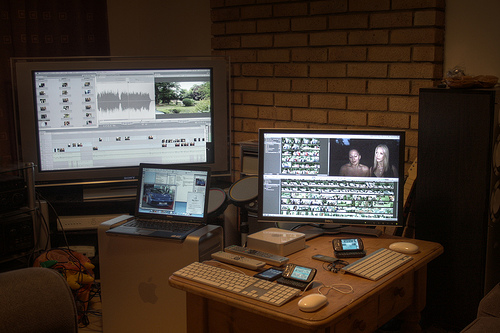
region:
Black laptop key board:
[123, 219, 198, 239]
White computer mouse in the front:
[297, 290, 329, 321]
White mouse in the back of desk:
[388, 237, 423, 255]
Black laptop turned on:
[107, 160, 208, 242]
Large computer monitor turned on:
[257, 128, 404, 223]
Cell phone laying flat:
[256, 264, 283, 284]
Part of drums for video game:
[207, 170, 259, 215]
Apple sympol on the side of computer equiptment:
[130, 264, 165, 309]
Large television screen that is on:
[8, 60, 233, 175]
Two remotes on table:
[212, 244, 288, 273]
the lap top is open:
[114, 155, 211, 246]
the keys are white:
[342, 224, 414, 281]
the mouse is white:
[292, 280, 339, 324]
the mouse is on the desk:
[277, 276, 342, 321]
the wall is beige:
[215, 13, 415, 175]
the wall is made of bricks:
[210, 10, 409, 157]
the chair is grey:
[0, 259, 87, 323]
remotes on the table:
[210, 237, 284, 271]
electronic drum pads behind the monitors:
[211, 170, 258, 220]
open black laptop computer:
[103, 160, 213, 243]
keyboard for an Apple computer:
[171, 260, 301, 308]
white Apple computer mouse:
[293, 285, 333, 316]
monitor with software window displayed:
[258, 129, 403, 224]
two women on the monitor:
[328, 136, 395, 179]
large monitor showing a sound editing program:
[34, 72, 214, 169]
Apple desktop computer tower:
[96, 208, 221, 331]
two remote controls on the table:
[210, 240, 285, 270]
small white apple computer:
[246, 223, 308, 258]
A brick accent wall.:
[217, 7, 432, 132]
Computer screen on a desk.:
[260, 131, 403, 226]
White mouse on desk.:
[296, 289, 328, 313]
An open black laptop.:
[109, 162, 219, 243]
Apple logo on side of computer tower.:
[134, 272, 160, 308]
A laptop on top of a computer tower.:
[104, 162, 214, 244]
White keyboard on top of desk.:
[174, 259, 300, 309]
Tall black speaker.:
[410, 85, 498, 325]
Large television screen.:
[13, 52, 231, 177]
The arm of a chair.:
[3, 259, 81, 329]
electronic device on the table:
[331, 236, 363, 256]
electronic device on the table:
[301, 291, 326, 314]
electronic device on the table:
[178, 253, 288, 310]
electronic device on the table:
[389, 230, 416, 257]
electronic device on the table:
[335, 237, 361, 259]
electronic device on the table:
[315, 247, 332, 260]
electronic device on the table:
[255, 122, 402, 235]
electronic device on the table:
[128, 169, 227, 247]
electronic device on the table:
[26, 56, 215, 165]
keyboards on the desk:
[181, 235, 407, 310]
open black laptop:
[108, 165, 210, 245]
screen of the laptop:
[133, 166, 203, 218]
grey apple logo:
[133, 267, 163, 304]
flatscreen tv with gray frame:
[12, 52, 234, 186]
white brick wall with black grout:
[210, 11, 435, 191]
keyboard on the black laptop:
[123, 217, 183, 232]